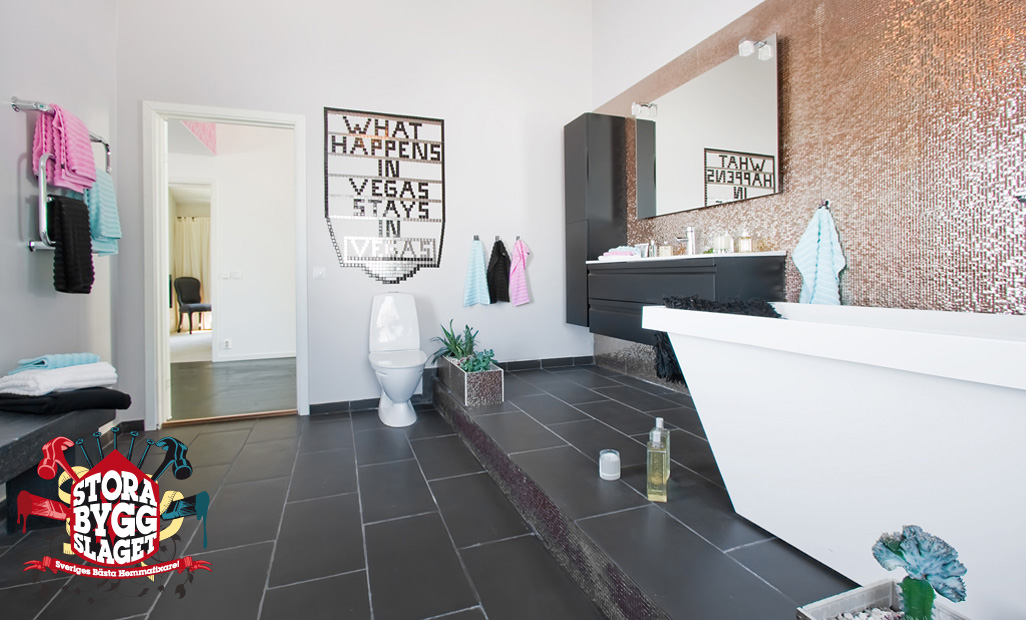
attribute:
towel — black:
[40, 100, 95, 191]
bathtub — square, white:
[523, 287, 1024, 607]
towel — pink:
[38, 119, 116, 208]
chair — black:
[169, 249, 251, 323]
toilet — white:
[354, 223, 443, 437]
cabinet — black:
[546, 151, 650, 298]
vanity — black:
[604, 233, 779, 298]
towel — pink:
[7, 97, 139, 156]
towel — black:
[14, 106, 166, 167]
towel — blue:
[0, 85, 124, 209]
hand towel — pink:
[462, 242, 523, 316]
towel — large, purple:
[27, 104, 96, 195]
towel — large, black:
[42, 192, 96, 294]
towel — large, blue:
[71, 166, 119, 257]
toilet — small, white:
[368, 289, 431, 428]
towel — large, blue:
[788, 207, 849, 307]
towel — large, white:
[1, 363, 122, 398]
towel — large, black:
[8, 386, 134, 421]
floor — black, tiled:
[4, 354, 856, 617]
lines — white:
[4, 354, 856, 617]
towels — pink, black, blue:
[27, 106, 122, 292]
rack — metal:
[6, 95, 116, 251]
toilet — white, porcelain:
[370, 289, 425, 428]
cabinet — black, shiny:
[562, 110, 623, 324]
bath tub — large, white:
[639, 296, 1021, 616]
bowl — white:
[370, 358, 437, 404]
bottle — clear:
[652, 411, 672, 483]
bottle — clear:
[642, 425, 675, 501]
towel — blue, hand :
[90, 164, 142, 264]